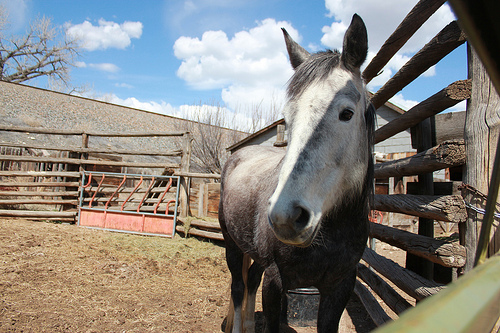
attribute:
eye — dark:
[336, 102, 355, 128]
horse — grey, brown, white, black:
[202, 14, 383, 332]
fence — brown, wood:
[324, 4, 500, 331]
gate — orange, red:
[81, 169, 182, 237]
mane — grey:
[292, 53, 341, 99]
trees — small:
[177, 106, 227, 186]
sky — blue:
[82, 2, 275, 96]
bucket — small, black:
[285, 286, 320, 326]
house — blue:
[219, 83, 425, 218]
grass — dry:
[1, 213, 347, 332]